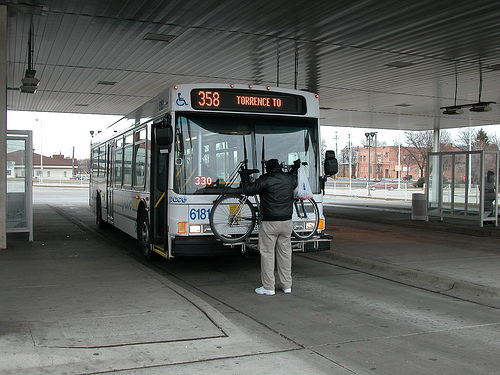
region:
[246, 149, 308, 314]
person standing in front of bus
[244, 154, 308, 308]
person with white shoes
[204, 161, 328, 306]
person mounting bike on bus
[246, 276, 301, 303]
pair of white shoes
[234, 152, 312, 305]
person wearing black coat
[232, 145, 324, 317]
person wearing tan pants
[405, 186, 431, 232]
large outdoor trash can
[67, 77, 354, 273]
large white bus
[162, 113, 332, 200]
large glass windshield on bus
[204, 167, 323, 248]
bike being mounted on bus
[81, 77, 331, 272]
the bus is white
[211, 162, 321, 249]
the bike is on the bus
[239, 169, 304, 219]
the man is wearing a jacket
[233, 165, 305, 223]
the jacket is black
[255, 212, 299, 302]
the man is wearing pants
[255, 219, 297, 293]
the pants are tan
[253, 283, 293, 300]
the man is wearing white shoes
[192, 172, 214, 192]
the bus has the number 330 in the window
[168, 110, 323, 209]
the bus has a windshield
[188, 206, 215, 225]
the bus has the number 6181 on the front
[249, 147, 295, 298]
man putting bike on bus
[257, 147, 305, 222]
man wearing a black jacket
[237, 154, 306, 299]
man wearing a hat putting bike on bus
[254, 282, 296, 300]
white tennis shoes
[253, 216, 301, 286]
brown slacks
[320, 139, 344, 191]
mirror on a bus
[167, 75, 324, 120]
number 358 bus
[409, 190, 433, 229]
A garbage can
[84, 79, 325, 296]
A man putting his bike on bus number 358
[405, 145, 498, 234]
A bus stop and garbage can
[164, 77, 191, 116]
Bus is handicap accessible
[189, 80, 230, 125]
Bus is number 358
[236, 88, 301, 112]
Bus travels from Torrence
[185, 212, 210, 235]
Bus has lights on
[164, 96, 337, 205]
Bus has a big windshield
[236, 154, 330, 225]
Man wearing black jacket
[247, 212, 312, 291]
Man wearing gray pants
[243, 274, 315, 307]
Man wearing white shoes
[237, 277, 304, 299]
Man wearing athletic shoe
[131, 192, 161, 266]
Bus has black tire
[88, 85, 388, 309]
man in front of bus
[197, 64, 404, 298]
bicycle in front of bus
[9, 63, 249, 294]
bus stop with bus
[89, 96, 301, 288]
open bus door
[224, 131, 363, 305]
man wearing white shoes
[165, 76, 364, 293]
bus with handicap sign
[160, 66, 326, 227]
bus with red lettering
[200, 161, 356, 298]
man has black jacket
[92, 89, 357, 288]
bus is white with blue writing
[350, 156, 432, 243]
red vehicle in parking lot